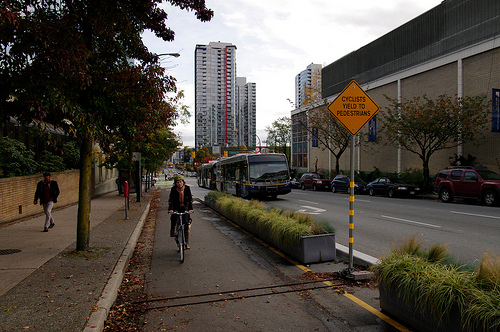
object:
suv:
[432, 166, 500, 207]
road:
[170, 167, 500, 277]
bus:
[213, 152, 294, 199]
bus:
[197, 162, 216, 190]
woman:
[166, 173, 193, 250]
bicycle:
[169, 209, 190, 263]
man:
[32, 173, 61, 233]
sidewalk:
[0, 182, 157, 332]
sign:
[328, 79, 379, 136]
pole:
[348, 135, 357, 269]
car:
[367, 173, 421, 199]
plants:
[202, 187, 335, 243]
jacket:
[33, 180, 60, 206]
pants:
[43, 201, 55, 228]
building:
[195, 41, 256, 157]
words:
[335, 95, 371, 117]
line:
[201, 200, 415, 331]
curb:
[82, 193, 154, 329]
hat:
[174, 174, 185, 181]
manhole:
[0, 248, 23, 257]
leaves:
[107, 184, 160, 329]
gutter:
[100, 189, 160, 332]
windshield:
[246, 159, 289, 183]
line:
[379, 214, 442, 230]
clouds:
[261, 11, 378, 66]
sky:
[1, 0, 441, 148]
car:
[328, 175, 368, 194]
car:
[300, 173, 330, 192]